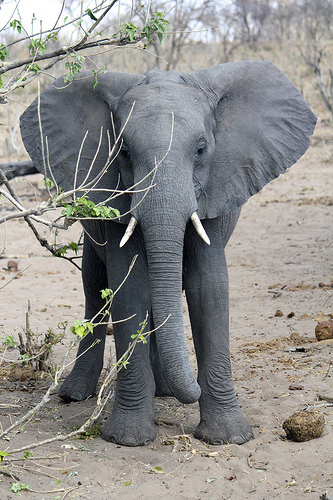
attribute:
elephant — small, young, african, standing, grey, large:
[18, 59, 317, 447]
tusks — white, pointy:
[118, 212, 212, 248]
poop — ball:
[281, 410, 325, 442]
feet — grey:
[59, 375, 253, 447]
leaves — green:
[1, 8, 172, 468]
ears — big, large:
[20, 60, 318, 226]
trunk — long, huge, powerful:
[140, 213, 203, 404]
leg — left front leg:
[190, 248, 256, 446]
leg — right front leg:
[102, 224, 159, 445]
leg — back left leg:
[149, 314, 178, 398]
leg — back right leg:
[59, 238, 111, 402]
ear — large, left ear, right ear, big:
[197, 58, 320, 221]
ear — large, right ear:
[18, 69, 138, 226]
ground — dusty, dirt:
[1, 109, 333, 499]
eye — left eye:
[194, 140, 208, 156]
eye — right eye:
[116, 141, 131, 155]